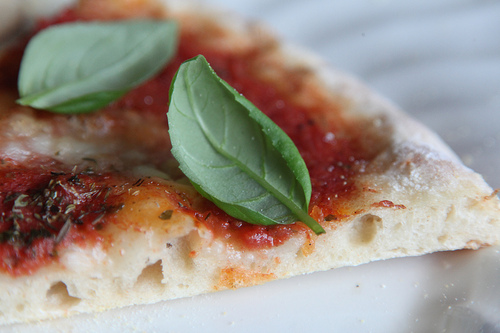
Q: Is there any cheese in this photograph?
A: Yes, there is cheese.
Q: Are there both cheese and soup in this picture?
A: No, there is cheese but no soup.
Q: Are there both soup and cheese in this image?
A: No, there is cheese but no soup.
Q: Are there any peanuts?
A: No, there are no peanuts.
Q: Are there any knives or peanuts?
A: No, there are no peanuts or knives.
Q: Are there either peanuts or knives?
A: No, there are no peanuts or knives.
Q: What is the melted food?
A: The food is cheese.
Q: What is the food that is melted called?
A: The food is cheese.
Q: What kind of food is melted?
A: The food is cheese.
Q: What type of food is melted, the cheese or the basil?
A: The cheese is melted.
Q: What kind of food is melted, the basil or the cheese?
A: The cheese is melted.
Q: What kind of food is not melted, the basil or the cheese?
A: The basil is not melted.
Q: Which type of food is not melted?
A: The food is basil.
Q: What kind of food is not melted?
A: The food is basil.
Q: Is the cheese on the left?
A: Yes, the cheese is on the left of the image.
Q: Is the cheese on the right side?
A: No, the cheese is on the left of the image.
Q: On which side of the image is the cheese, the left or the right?
A: The cheese is on the left of the image.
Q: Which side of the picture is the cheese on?
A: The cheese is on the left of the image.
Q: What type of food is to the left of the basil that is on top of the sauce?
A: The food is cheese.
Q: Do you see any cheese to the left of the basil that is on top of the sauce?
A: Yes, there is cheese to the left of the basil.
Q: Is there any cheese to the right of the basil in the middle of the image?
A: No, the cheese is to the left of the basil.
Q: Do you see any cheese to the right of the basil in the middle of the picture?
A: No, the cheese is to the left of the basil.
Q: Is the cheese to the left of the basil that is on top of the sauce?
A: Yes, the cheese is to the left of the basil.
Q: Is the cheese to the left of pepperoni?
A: No, the cheese is to the left of the basil.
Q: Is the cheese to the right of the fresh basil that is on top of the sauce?
A: No, the cheese is to the left of the basil.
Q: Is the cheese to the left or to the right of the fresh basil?
A: The cheese is to the left of the basil.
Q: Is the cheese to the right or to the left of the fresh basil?
A: The cheese is to the left of the basil.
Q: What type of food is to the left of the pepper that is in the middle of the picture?
A: The food is cheese.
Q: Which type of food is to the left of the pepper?
A: The food is cheese.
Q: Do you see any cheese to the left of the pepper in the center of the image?
A: Yes, there is cheese to the left of the pepper.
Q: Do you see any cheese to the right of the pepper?
A: No, the cheese is to the left of the pepper.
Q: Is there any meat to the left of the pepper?
A: No, there is cheese to the left of the pepper.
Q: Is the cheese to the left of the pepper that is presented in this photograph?
A: Yes, the cheese is to the left of the pepper.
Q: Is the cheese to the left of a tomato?
A: No, the cheese is to the left of the pepper.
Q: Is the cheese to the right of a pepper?
A: No, the cheese is to the left of a pepper.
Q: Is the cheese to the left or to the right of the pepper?
A: The cheese is to the left of the pepper.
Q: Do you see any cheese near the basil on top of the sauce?
A: Yes, there is cheese near the basil.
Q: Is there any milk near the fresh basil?
A: No, there is cheese near the basil.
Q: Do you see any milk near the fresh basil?
A: No, there is cheese near the basil.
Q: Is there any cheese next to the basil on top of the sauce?
A: Yes, there is cheese next to the basil.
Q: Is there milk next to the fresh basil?
A: No, there is cheese next to the basil.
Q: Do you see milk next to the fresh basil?
A: No, there is cheese next to the basil.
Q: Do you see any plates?
A: Yes, there is a plate.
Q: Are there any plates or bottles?
A: Yes, there is a plate.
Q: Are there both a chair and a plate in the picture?
A: No, there is a plate but no chairs.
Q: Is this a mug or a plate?
A: This is a plate.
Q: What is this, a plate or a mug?
A: This is a plate.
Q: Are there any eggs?
A: No, there are no eggs.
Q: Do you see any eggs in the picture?
A: No, there are no eggs.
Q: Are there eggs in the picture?
A: No, there are no eggs.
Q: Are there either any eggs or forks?
A: No, there are no eggs or forks.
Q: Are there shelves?
A: No, there are no shelves.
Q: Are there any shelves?
A: No, there are no shelves.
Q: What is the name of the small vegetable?
A: The vegetable is basil.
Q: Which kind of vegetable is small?
A: The vegetable is basil.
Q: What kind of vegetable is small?
A: The vegetable is basil.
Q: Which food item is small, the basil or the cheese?
A: The basil is small.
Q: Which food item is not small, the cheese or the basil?
A: The cheese is not small.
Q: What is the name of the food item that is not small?
A: The food item is cheese.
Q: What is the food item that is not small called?
A: The food item is cheese.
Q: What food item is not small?
A: The food item is cheese.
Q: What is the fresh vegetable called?
A: The vegetable is basil.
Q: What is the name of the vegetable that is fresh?
A: The vegetable is basil.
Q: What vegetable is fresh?
A: The vegetable is basil.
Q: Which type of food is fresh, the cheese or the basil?
A: The basil is fresh.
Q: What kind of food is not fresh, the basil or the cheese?
A: The cheese is not fresh.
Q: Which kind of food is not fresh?
A: The food is cheese.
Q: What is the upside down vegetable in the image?
A: The vegetable is basil.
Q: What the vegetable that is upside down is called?
A: The vegetable is basil.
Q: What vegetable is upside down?
A: The vegetable is basil.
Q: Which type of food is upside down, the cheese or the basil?
A: The basil is upside down.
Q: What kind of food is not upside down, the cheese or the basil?
A: The cheese is not upside down.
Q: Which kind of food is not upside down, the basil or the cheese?
A: The cheese is not upside down.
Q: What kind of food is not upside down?
A: The food is cheese.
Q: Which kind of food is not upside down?
A: The food is cheese.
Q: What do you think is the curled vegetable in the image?
A: The vegetable is basil.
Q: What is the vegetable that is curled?
A: The vegetable is basil.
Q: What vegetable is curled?
A: The vegetable is basil.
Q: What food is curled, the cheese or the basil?
A: The basil is curled.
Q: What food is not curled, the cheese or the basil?
A: The cheese is not curled.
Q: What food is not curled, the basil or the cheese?
A: The cheese is not curled.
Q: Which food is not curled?
A: The food is cheese.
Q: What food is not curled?
A: The food is cheese.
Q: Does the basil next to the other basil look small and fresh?
A: Yes, the basil is small and fresh.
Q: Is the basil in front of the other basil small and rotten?
A: No, the basil is small but fresh.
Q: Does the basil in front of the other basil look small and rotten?
A: No, the basil is small but fresh.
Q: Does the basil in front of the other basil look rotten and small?
A: No, the basil is small but fresh.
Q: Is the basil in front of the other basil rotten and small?
A: No, the basil is small but fresh.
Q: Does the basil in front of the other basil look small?
A: Yes, the basil is small.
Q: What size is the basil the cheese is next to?
A: The basil is small.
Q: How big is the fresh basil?
A: The basil is small.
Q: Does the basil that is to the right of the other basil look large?
A: No, the basil is small.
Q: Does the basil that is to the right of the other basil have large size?
A: No, the basil is small.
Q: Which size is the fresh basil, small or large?
A: The basil is small.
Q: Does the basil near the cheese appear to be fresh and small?
A: Yes, the basil is fresh and small.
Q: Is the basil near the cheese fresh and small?
A: Yes, the basil is fresh and small.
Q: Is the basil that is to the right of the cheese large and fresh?
A: No, the basil is fresh but small.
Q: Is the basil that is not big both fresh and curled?
A: Yes, the basil is fresh and curled.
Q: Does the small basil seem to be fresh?
A: Yes, the basil is fresh.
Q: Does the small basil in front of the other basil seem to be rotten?
A: No, the basil is fresh.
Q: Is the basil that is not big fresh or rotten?
A: The basil is fresh.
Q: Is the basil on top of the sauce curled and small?
A: Yes, the basil is curled and small.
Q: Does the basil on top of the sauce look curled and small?
A: Yes, the basil is curled and small.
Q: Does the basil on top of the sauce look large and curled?
A: No, the basil is curled but small.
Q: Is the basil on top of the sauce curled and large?
A: No, the basil is curled but small.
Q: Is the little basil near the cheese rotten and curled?
A: No, the basil is curled but fresh.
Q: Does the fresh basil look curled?
A: Yes, the basil is curled.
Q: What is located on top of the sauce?
A: The basil is on top of the sauce.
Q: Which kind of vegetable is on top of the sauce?
A: The vegetable is basil.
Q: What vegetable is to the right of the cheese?
A: The vegetable is basil.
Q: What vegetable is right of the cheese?
A: The vegetable is basil.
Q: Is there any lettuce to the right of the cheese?
A: No, there is basil to the right of the cheese.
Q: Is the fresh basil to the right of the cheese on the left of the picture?
A: Yes, the basil is to the right of the cheese.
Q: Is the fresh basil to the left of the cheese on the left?
A: No, the basil is to the right of the cheese.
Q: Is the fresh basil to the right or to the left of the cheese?
A: The basil is to the right of the cheese.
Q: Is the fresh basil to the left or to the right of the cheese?
A: The basil is to the right of the cheese.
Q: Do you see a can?
A: No, there are no cans.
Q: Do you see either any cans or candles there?
A: No, there are no cans or candles.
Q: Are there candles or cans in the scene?
A: No, there are no cans or candles.